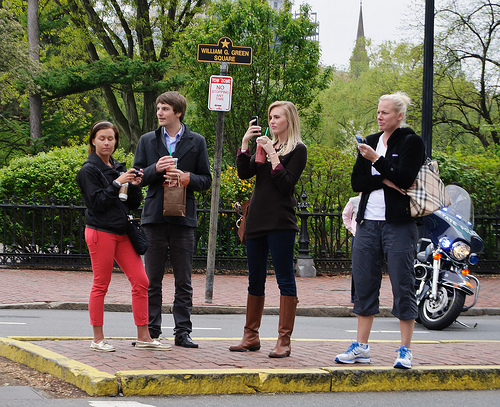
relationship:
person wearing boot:
[228, 100, 309, 360] [266, 292, 302, 357]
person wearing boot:
[228, 100, 309, 360] [224, 289, 271, 356]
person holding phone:
[228, 100, 309, 360] [246, 115, 259, 139]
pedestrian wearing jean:
[74, 119, 176, 354] [86, 225, 147, 325]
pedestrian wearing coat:
[124, 90, 214, 350] [128, 124, 213, 233]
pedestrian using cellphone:
[74, 119, 176, 354] [127, 165, 142, 179]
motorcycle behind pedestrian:
[416, 181, 484, 327] [124, 90, 214, 350]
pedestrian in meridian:
[124, 90, 214, 350] [1, 328, 483, 396]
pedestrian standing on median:
[124, 90, 214, 350] [0, 336, 499, 396]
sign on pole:
[193, 42, 253, 64] [203, 59, 227, 301]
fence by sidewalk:
[6, 187, 498, 268] [5, 250, 497, 314]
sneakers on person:
[335, 343, 413, 368] [334, 90, 427, 368]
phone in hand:
[247, 112, 264, 125] [241, 118, 266, 144]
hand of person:
[241, 118, 266, 144] [228, 100, 309, 360]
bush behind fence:
[227, 137, 368, 266] [0, 185, 495, 274]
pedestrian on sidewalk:
[74, 119, 176, 354] [1, 334, 498, 395]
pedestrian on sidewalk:
[124, 90, 214, 350] [1, 334, 498, 395]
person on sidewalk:
[229, 100, 308, 358] [1, 334, 498, 395]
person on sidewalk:
[334, 90, 427, 368] [1, 334, 498, 395]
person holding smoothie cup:
[228, 100, 309, 360] [253, 139, 266, 169]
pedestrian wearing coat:
[124, 90, 214, 350] [133, 121, 213, 228]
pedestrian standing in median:
[79, 114, 191, 353] [2, 322, 496, 397]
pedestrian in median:
[124, 85, 214, 352] [0, 336, 499, 396]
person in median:
[228, 100, 309, 360] [0, 336, 499, 396]